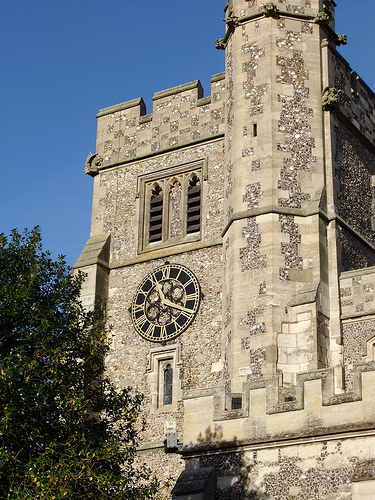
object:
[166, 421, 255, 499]
shade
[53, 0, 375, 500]
building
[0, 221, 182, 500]
tree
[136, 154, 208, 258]
window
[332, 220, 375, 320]
balcony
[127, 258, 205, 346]
clock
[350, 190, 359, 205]
rocks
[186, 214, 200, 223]
vents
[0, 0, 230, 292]
sky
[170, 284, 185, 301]
circle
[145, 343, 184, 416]
window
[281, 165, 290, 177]
blocks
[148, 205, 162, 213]
panels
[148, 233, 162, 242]
downwards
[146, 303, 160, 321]
circles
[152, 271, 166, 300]
hands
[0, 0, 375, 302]
morning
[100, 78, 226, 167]
pattern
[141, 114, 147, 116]
cutouts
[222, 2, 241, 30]
figures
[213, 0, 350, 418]
tower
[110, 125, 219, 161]
surface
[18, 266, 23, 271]
leaves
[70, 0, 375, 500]
wall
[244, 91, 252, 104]
stones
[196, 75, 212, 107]
opening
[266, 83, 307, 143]
stone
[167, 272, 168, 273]
numerals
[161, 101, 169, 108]
parapets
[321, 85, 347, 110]
gargoyles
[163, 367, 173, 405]
glass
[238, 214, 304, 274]
decoration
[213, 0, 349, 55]
top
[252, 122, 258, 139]
hole